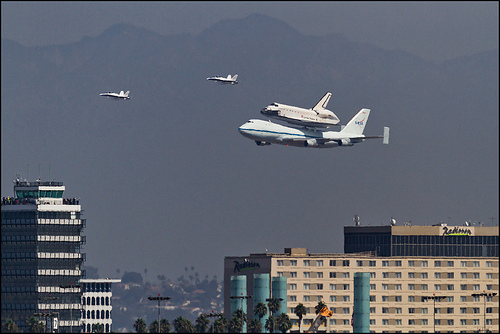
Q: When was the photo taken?
A: Daytime.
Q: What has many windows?
A: Building.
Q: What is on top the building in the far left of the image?
A: People.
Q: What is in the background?
A: Mountains.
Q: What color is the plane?
A: White and blue.